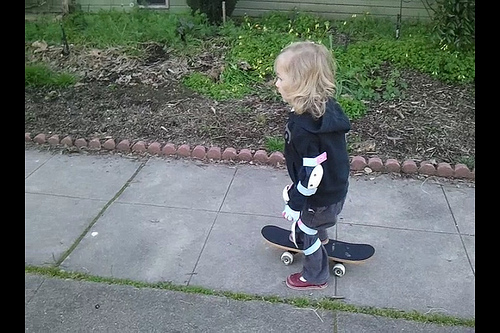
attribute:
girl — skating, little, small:
[271, 41, 352, 290]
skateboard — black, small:
[259, 224, 373, 282]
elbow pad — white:
[304, 161, 324, 189]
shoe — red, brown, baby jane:
[285, 270, 327, 291]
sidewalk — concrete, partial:
[26, 145, 475, 323]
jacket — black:
[282, 113, 349, 206]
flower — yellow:
[425, 31, 452, 77]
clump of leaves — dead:
[33, 34, 231, 88]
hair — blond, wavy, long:
[276, 42, 338, 115]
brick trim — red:
[25, 132, 477, 182]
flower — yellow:
[401, 48, 415, 70]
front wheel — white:
[281, 251, 295, 264]